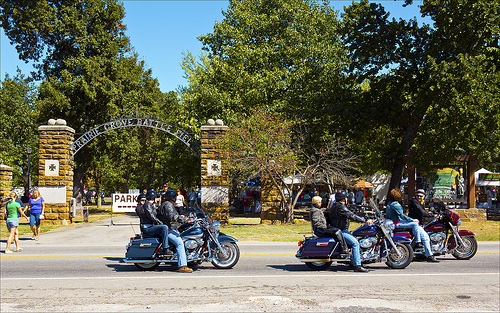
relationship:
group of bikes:
[112, 185, 476, 264] [121, 208, 477, 265]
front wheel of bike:
[388, 240, 414, 267] [296, 203, 412, 271]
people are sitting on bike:
[309, 189, 363, 271] [296, 203, 412, 271]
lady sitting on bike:
[311, 194, 342, 247] [296, 203, 412, 271]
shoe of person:
[180, 263, 192, 272] [161, 189, 201, 272]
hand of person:
[183, 214, 198, 225] [161, 189, 201, 272]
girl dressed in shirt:
[4, 192, 22, 253] [7, 202, 22, 221]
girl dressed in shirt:
[21, 188, 48, 242] [29, 197, 43, 212]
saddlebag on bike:
[308, 228, 336, 243] [296, 203, 412, 271]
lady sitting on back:
[306, 194, 354, 258] [296, 221, 343, 271]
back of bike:
[296, 221, 343, 271] [296, 203, 412, 271]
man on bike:
[332, 191, 366, 270] [296, 203, 412, 271]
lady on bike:
[306, 194, 354, 258] [296, 203, 412, 271]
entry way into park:
[37, 117, 228, 229] [14, 58, 488, 210]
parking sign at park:
[112, 193, 155, 211] [14, 58, 488, 210]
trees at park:
[0, 3, 490, 190] [14, 58, 488, 210]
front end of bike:
[362, 212, 414, 268] [296, 203, 412, 271]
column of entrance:
[35, 123, 72, 220] [37, 117, 228, 229]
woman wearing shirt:
[4, 192, 22, 253] [7, 202, 22, 221]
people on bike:
[309, 189, 363, 271] [296, 203, 412, 271]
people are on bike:
[309, 189, 363, 271] [296, 203, 412, 271]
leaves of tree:
[455, 84, 486, 108] [292, 4, 498, 209]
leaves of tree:
[475, 14, 495, 38] [292, 4, 498, 209]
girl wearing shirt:
[21, 188, 48, 242] [29, 197, 43, 212]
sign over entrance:
[70, 117, 199, 157] [37, 117, 228, 229]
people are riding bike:
[309, 189, 363, 271] [296, 203, 412, 271]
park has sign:
[14, 58, 488, 210] [70, 117, 199, 157]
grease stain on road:
[293, 297, 407, 312] [0, 246, 498, 310]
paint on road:
[2, 248, 499, 260] [0, 246, 498, 310]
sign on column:
[70, 117, 199, 157] [35, 123, 72, 220]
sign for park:
[70, 117, 199, 157] [14, 58, 488, 210]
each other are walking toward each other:
[3, 192, 32, 255] [2, 187, 45, 253]